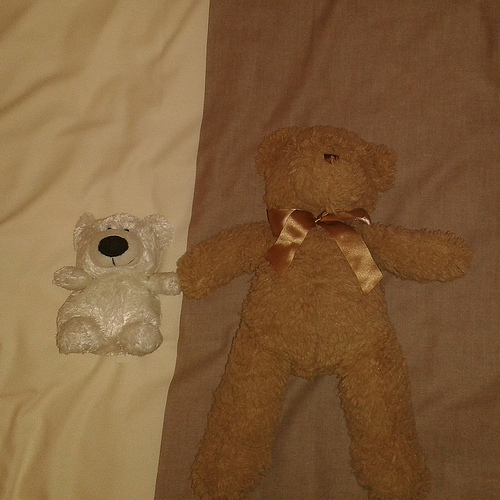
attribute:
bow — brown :
[254, 203, 431, 316]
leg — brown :
[302, 280, 403, 488]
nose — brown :
[273, 123, 432, 237]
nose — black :
[307, 130, 372, 167]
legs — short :
[38, 291, 188, 374]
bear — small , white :
[218, 69, 444, 452]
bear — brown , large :
[171, 71, 456, 491]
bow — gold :
[267, 205, 368, 277]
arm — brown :
[376, 180, 482, 330]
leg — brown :
[296, 337, 431, 488]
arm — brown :
[185, 188, 243, 287]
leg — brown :
[184, 343, 314, 494]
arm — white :
[174, 184, 263, 315]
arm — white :
[162, 180, 270, 350]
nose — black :
[299, 130, 353, 180]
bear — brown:
[195, 120, 445, 495]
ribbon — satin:
[268, 194, 434, 324]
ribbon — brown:
[270, 212, 420, 302]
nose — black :
[310, 114, 371, 187]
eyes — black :
[281, 123, 412, 193]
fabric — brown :
[198, 17, 473, 493]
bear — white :
[178, 86, 450, 477]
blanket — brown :
[154, 25, 463, 497]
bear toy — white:
[53, 210, 179, 354]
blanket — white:
[1, 2, 209, 499]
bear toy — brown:
[175, 125, 469, 496]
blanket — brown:
[154, 1, 498, 499]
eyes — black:
[104, 226, 131, 232]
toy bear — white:
[50, 213, 178, 354]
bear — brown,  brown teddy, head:
[172, 123, 472, 495]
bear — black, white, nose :
[50, 212, 180, 355]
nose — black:
[98, 235, 129, 256]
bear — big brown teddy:
[170, 106, 483, 486]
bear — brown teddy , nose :
[317, 143, 340, 162]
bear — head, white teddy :
[24, 217, 201, 362]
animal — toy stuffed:
[37, 210, 196, 365]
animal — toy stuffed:
[52, 200, 188, 360]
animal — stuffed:
[154, 260, 199, 293]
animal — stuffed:
[49, 201, 191, 372]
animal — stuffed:
[165, 134, 483, 492]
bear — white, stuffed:
[48, 190, 175, 358]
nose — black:
[96, 226, 142, 262]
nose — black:
[37, 190, 184, 350]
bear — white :
[52, 204, 173, 351]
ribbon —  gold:
[267, 206, 309, 275]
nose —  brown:
[304, 140, 355, 178]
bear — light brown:
[49, 206, 190, 373]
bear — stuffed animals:
[38, 198, 178, 364]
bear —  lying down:
[30, 138, 483, 476]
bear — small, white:
[61, 207, 171, 377]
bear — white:
[55, 199, 221, 379]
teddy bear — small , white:
[19, 194, 203, 363]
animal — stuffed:
[42, 203, 192, 363]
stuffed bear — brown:
[172, 117, 476, 498]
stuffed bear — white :
[28, 199, 178, 366]